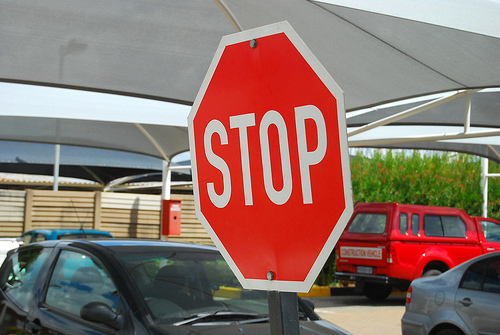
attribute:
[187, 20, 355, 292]
stop sign — red, stop sign, road, white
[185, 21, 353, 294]
border — white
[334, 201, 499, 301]
truck — red, chevrolet, parked, white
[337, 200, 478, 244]
camper shell — red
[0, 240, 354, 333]
car — black, parked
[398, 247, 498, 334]
car — silver, parked, gray, small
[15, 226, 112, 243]
vehicle — blue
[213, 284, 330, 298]
curb — yellow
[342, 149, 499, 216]
hedges — green, red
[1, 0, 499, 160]
roof — grey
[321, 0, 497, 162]
sky — blue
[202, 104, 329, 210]
letters — white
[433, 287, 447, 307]
gas tank door — closed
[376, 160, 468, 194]
flowers — red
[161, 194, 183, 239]
box — red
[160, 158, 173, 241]
pole — grey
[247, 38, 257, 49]
bolt — silver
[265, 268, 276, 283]
bolt — silver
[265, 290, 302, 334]
pole — metal, black, gray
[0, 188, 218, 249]
fence — wood, brown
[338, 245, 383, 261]
sign — white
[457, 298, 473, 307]
door handle — silver, small